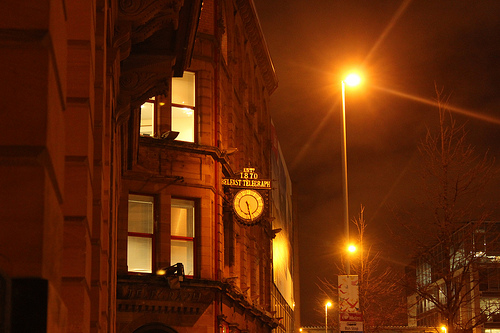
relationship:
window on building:
[113, 189, 200, 281] [2, 0, 301, 332]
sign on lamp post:
[335, 273, 373, 330] [331, 73, 372, 266]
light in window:
[164, 191, 202, 239] [160, 54, 207, 141]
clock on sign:
[230, 187, 265, 222] [208, 157, 284, 193]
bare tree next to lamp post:
[315, 215, 394, 321] [337, 73, 351, 274]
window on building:
[126, 188, 200, 279] [2, 0, 301, 332]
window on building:
[137, 63, 214, 145] [2, 0, 301, 332]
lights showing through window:
[174, 68, 219, 202] [123, 100, 197, 308]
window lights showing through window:
[128, 70, 195, 275] [123, 100, 197, 308]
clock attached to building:
[228, 187, 270, 226] [3, 7, 223, 326]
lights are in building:
[341, 238, 360, 255] [398, 215, 495, 331]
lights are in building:
[340, 66, 363, 90] [398, 215, 495, 331]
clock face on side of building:
[193, 131, 286, 230] [72, 59, 303, 331]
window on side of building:
[126, 188, 200, 279] [129, 58, 209, 292]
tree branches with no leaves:
[324, 239, 470, 289] [365, 205, 383, 233]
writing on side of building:
[338, 312, 361, 319] [256, 126, 303, 331]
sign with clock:
[220, 167, 275, 194] [227, 190, 269, 223]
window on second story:
[137, 63, 201, 145] [115, 51, 306, 217]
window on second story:
[126, 188, 200, 279] [115, 51, 306, 217]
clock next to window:
[228, 187, 270, 226] [123, 180, 204, 273]